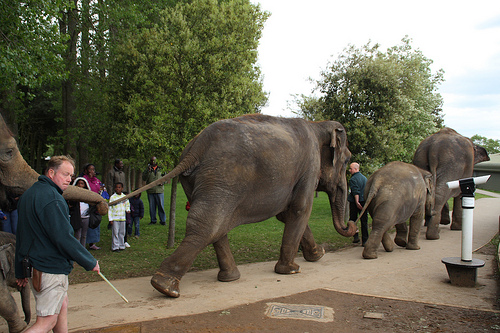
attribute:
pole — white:
[458, 193, 478, 267]